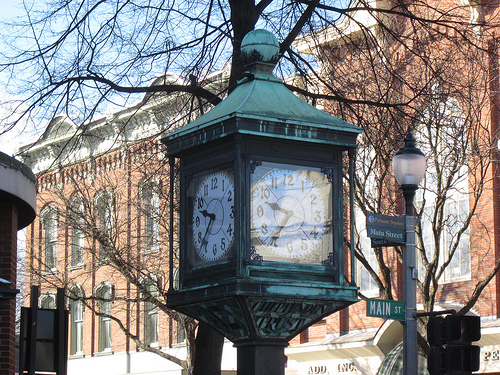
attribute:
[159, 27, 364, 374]
clock — white, large, decorative, old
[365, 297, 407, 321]
sign — green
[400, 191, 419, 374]
pole — grey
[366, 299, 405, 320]
sign — green, large, gree, behind, back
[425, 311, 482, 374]
walk light — black, red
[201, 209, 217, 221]
hand — black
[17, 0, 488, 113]
tree — bare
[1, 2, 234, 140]
sky — blue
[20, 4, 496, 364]
building — back